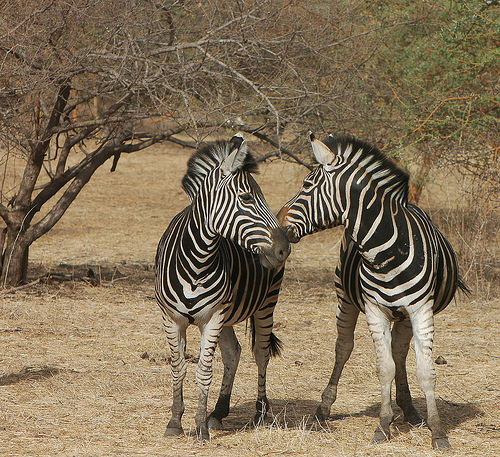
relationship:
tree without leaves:
[4, 2, 495, 286] [7, 5, 496, 158]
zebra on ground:
[156, 135, 288, 444] [0, 153, 493, 456]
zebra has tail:
[156, 135, 288, 444] [245, 321, 283, 357]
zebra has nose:
[156, 135, 288, 444] [241, 223, 299, 271]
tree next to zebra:
[4, 2, 495, 286] [156, 135, 288, 444]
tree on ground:
[4, 2, 495, 286] [0, 153, 493, 456]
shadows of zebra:
[234, 386, 474, 439] [156, 135, 288, 444]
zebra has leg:
[156, 135, 288, 444] [165, 314, 223, 435]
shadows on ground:
[234, 386, 474, 439] [0, 153, 493, 456]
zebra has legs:
[156, 135, 288, 444] [151, 318, 445, 451]